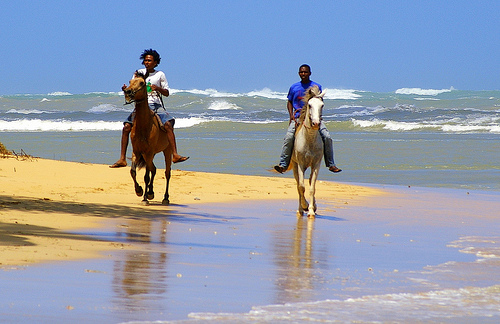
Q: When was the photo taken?
A: Daytime.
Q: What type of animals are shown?
A: Horses.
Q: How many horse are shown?
A: Two.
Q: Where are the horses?
A: Beach.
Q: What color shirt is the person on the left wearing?
A: Blue.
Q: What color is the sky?
A: Blue.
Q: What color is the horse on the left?
A: Brown.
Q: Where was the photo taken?
A: On a beach.